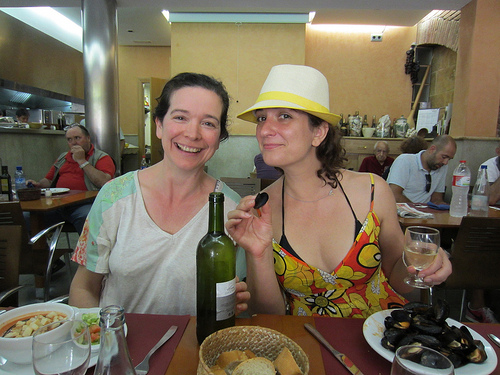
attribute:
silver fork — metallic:
[131, 322, 178, 374]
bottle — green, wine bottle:
[191, 189, 244, 343]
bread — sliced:
[191, 322, 296, 370]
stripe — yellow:
[243, 92, 334, 109]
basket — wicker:
[195, 323, 315, 373]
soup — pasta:
[8, 301, 95, 333]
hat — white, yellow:
[228, 61, 361, 135]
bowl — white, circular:
[1, 286, 71, 358]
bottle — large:
[146, 172, 252, 352]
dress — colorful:
[265, 187, 403, 319]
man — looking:
[363, 132, 458, 210]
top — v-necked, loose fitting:
[68, 169, 247, 314]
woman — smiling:
[158, 69, 224, 172]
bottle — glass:
[252, 187, 272, 220]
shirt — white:
[72, 170, 244, 317]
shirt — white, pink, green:
[71, 185, 222, 312]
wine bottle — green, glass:
[193, 181, 242, 353]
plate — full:
[357, 306, 499, 374]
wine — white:
[401, 243, 439, 270]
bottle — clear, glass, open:
[95, 302, 135, 368]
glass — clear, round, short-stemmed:
[401, 223, 441, 291]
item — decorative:
[374, 111, 394, 137]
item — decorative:
[347, 110, 364, 137]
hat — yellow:
[236, 62, 340, 127]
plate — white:
[360, 302, 483, 369]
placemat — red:
[124, 310, 195, 369]